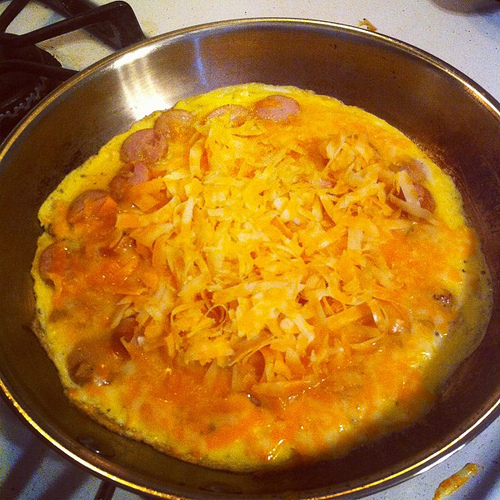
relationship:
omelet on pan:
[32, 82, 477, 474] [0, 17, 499, 498]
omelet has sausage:
[32, 82, 477, 474] [257, 94, 301, 118]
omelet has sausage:
[32, 82, 477, 474] [162, 114, 198, 141]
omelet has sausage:
[32, 82, 477, 474] [68, 189, 109, 217]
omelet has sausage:
[32, 82, 477, 474] [120, 129, 156, 158]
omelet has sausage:
[32, 82, 477, 474] [38, 238, 73, 282]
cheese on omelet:
[120, 119, 434, 392] [32, 82, 477, 474]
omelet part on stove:
[435, 463, 476, 499] [0, 0, 497, 499]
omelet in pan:
[32, 82, 477, 474] [0, 17, 499, 498]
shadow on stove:
[2, 400, 89, 498] [0, 0, 497, 499]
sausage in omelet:
[257, 94, 301, 118] [32, 82, 477, 474]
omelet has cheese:
[32, 82, 477, 474] [120, 119, 434, 392]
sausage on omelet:
[257, 94, 301, 118] [32, 82, 477, 474]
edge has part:
[97, 2, 147, 46] [116, 4, 126, 18]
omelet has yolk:
[32, 82, 477, 474] [398, 372, 429, 412]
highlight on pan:
[105, 46, 173, 121] [0, 17, 499, 498]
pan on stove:
[0, 17, 499, 498] [0, 0, 497, 499]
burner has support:
[0, 0, 145, 142] [3, 0, 147, 135]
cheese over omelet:
[120, 119, 434, 392] [32, 82, 477, 474]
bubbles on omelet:
[58, 170, 103, 188] [32, 82, 477, 474]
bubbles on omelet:
[460, 261, 495, 307] [32, 82, 477, 474]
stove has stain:
[0, 0, 497, 499] [362, 18, 376, 31]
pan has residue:
[0, 17, 499, 498] [149, 489, 183, 499]